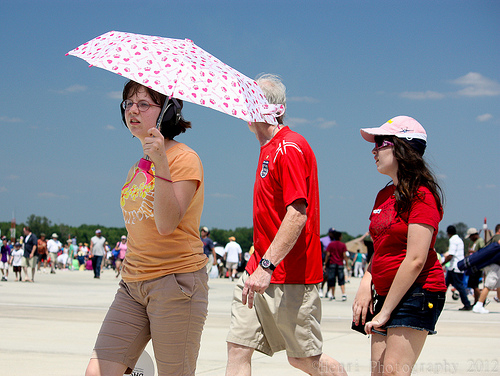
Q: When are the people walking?
A: Daytime.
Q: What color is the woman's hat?
A: Pink.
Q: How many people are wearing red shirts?
A: Two.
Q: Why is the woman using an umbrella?
A: Shade.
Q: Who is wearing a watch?
A: The man.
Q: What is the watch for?
A: Tell time.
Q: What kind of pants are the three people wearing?
A: Shorts.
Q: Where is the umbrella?
A: Over the woman's head.